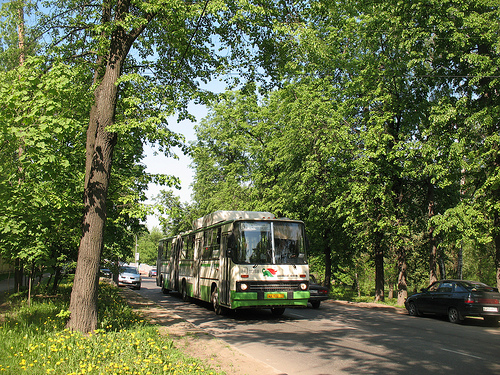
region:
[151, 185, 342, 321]
bus on a street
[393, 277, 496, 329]
car on a street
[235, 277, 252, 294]
light on a bus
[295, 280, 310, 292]
light on a bus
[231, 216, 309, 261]
window on a bus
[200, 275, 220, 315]
tire on a bus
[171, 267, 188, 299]
tire on a bus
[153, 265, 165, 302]
tire on a bus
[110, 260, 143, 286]
car on a street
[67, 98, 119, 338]
brown tree trunk near a street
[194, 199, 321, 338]
a green and white bus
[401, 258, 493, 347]
a black car parked on the side of a street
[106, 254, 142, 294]
a white car parked on the side of a street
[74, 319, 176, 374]
yellow flowers next to a street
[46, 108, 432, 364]
a street with trees on both sides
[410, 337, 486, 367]
a white line painted on a street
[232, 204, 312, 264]
a windshield on a bus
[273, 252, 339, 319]
a car next to a bus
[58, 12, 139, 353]
a large tree trunk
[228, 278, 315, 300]
headlights on a bus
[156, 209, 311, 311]
A bus on the road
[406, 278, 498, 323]
A black car near the bus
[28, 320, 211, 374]
Yellow flowers by the tree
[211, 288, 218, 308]
The front wheel of the bus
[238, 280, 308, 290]
Headlights on the bus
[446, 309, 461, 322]
The rear tire of the black car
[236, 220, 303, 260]
Windows at the front of the bus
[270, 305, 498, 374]
A shadow on the road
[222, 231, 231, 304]
A door on the side of the bus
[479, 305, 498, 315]
A white license plate behind the car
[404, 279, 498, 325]
Black car parked on the side of the road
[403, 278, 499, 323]
Black car parked under many leafy trees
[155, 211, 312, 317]
Green bus driving between many green trees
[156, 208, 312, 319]
Bus driving on a road between parked cars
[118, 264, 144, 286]
White car parked on the side of the road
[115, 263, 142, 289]
White car parked next to many trees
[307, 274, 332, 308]
Black car passing next to large bus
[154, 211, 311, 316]
White bus with green along the bottom on road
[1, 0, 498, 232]
Bright blue sky behind leafy trees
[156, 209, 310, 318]
Bus passing next to black car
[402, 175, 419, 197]
part of a tree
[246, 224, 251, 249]
part of a window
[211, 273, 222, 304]
part of a wheel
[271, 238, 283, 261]
edge of a window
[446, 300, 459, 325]
part of a wheel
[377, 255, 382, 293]
part of a stem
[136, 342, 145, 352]
part of a bush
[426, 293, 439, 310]
part of a door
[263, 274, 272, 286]
edge of a bus